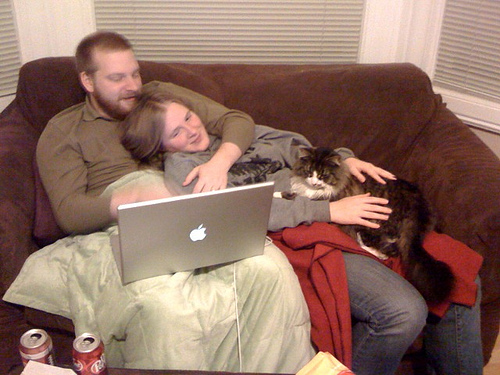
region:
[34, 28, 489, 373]
two people cuddling on the couch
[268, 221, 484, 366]
red blanket on the girl's lap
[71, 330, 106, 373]
red Dr Pepper soda can on the table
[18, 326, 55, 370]
brown football soda can on the table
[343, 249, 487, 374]
blue jeans on the woman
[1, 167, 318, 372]
white blanket on the man's lap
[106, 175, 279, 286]
silver laptop on the man's lap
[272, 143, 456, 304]
white and black cat on the woman's lap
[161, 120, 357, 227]
woman wearing a gray sweatshirt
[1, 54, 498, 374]
brown couch with people sitting on it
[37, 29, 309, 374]
Man sitting on the couch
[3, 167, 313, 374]
Blanket on the man's lap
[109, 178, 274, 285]
Computer on the man's lap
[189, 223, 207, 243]
Apple logo on the computer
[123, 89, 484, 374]
Woman lying in the man's arm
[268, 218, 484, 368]
Blanket on the woman's lap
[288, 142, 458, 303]
Cat lying on the woman's lap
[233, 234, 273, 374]
White cable on the computer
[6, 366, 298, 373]
Table in front the couch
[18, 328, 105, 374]
Two cans of cola on the table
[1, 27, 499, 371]
Two people sitting on a couch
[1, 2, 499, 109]
The white blinds are closed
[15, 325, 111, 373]
Two open soda cans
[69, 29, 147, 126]
The man has a beard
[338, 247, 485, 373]
A pair of blue jeans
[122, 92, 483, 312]
A cat on a woman's lap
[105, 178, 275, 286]
A gray Apple laptop computer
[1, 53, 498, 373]
The couch is brown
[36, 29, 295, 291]
Laptop computer on a man's lap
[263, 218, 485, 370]
A blanket is red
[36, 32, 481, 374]
a man hugging a woman on a couch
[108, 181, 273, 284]
a silver laptop on a man's lap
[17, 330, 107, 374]
two bottle of soda on a table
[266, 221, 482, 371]
a red blanket on woman's lap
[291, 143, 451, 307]
a cat on a red blanket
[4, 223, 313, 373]
a white blanket on man's lap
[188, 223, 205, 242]
white logo of an apple on a laptop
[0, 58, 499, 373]
a brown couch in a living room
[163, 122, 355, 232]
woman wearing a gray sweater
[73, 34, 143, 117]
man with short brown beard and hair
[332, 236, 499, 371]
Woman wearing pants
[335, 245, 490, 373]
Woman is wearing pants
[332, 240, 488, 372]
Woman wearing blue pants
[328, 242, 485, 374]
Woman is wearing blue pants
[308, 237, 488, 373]
Woman wearing jeans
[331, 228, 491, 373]
Woman is wearing jeans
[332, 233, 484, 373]
Woman wearing blue jeans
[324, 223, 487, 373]
Woman is wearing blue jeans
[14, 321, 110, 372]
Cans are on a table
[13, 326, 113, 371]
Soda cans are on a table